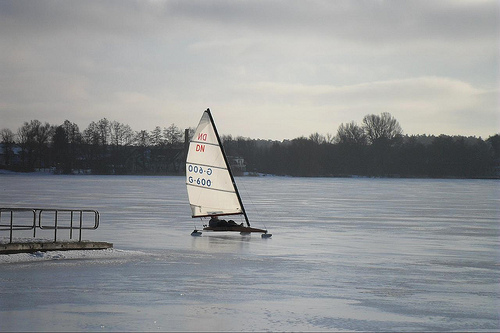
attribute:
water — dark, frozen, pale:
[2, 170, 499, 332]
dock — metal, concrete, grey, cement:
[1, 208, 113, 256]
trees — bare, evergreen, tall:
[1, 110, 406, 157]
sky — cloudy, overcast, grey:
[1, 1, 498, 137]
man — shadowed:
[204, 212, 246, 228]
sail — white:
[184, 107, 243, 215]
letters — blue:
[186, 163, 215, 189]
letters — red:
[194, 133, 208, 154]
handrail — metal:
[0, 207, 102, 239]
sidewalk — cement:
[1, 243, 113, 251]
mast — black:
[206, 110, 251, 229]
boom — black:
[190, 212, 250, 216]